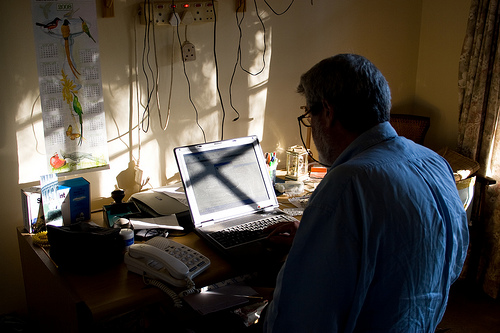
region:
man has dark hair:
[300, 46, 400, 86]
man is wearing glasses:
[289, 96, 357, 179]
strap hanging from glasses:
[291, 90, 350, 173]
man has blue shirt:
[317, 149, 462, 331]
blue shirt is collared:
[334, 116, 411, 165]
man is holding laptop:
[180, 143, 295, 280]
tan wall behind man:
[160, 40, 213, 153]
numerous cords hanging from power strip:
[137, 13, 303, 139]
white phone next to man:
[131, 233, 231, 299]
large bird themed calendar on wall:
[21, 3, 117, 168]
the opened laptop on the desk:
[174, 135, 300, 270]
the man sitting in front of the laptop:
[266, 53, 469, 331]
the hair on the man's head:
[295, 54, 390, 134]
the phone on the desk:
[123, 235, 208, 296]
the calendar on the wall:
[27, 2, 109, 176]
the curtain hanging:
[458, 1, 498, 313]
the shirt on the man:
[263, 122, 468, 332]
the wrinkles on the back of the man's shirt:
[387, 184, 469, 332]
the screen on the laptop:
[182, 144, 269, 214]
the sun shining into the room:
[2, 0, 497, 332]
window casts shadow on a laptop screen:
[168, 145, 283, 216]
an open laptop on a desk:
[173, 135, 295, 251]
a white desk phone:
[126, 233, 210, 290]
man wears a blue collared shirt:
[264, 127, 474, 332]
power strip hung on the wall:
[130, 5, 226, 27]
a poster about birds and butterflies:
[35, 8, 100, 168]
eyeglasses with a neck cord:
[295, 110, 325, 170]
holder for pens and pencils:
[260, 141, 279, 184]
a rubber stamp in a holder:
[100, 188, 140, 221]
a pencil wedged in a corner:
[36, 243, 62, 270]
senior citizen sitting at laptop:
[272, 54, 389, 331]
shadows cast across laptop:
[182, 141, 266, 211]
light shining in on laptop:
[177, 130, 269, 200]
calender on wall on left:
[19, 9, 121, 184]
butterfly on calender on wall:
[52, 113, 86, 143]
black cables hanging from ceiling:
[127, 37, 264, 124]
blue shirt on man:
[320, 120, 462, 325]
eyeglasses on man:
[274, 99, 332, 152]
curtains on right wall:
[461, 27, 496, 166]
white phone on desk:
[131, 234, 184, 296]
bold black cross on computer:
[157, 135, 290, 209]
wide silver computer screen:
[160, 124, 303, 226]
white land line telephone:
[127, 223, 201, 291]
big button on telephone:
[173, 244, 205, 262]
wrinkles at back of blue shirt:
[388, 172, 458, 285]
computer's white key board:
[224, 221, 282, 239]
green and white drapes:
[452, 39, 486, 111]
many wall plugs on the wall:
[138, 4, 266, 63]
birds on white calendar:
[29, 21, 118, 160]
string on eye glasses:
[279, 112, 346, 173]